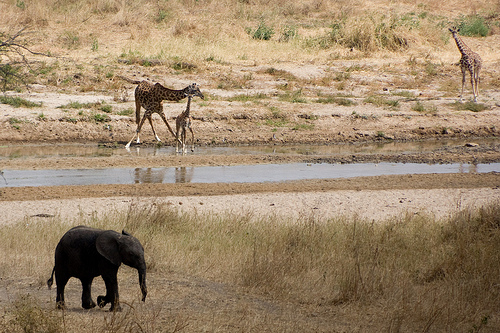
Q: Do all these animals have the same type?
A: No, there are both giraffes and elephants.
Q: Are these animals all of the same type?
A: No, there are both giraffes and elephants.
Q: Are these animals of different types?
A: Yes, they are giraffes and elephants.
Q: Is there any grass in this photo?
A: Yes, there is grass.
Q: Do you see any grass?
A: Yes, there is grass.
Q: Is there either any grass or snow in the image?
A: Yes, there is grass.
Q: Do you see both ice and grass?
A: No, there is grass but no ice.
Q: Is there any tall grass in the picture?
A: Yes, there is tall grass.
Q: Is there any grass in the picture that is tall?
A: Yes, there is grass that is tall.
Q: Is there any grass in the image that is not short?
A: Yes, there is tall grass.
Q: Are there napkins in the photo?
A: No, there are no napkins.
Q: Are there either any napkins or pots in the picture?
A: No, there are no napkins or pots.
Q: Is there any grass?
A: Yes, there is grass.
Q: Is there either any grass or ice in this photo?
A: Yes, there is grass.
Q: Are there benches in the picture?
A: No, there are no benches.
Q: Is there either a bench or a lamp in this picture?
A: No, there are no benches or lamps.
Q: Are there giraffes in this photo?
A: Yes, there is a giraffe.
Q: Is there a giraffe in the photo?
A: Yes, there is a giraffe.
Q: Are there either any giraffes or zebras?
A: Yes, there is a giraffe.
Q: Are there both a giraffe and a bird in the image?
A: No, there is a giraffe but no birds.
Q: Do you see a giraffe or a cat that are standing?
A: Yes, the giraffe is standing.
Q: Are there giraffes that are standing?
A: Yes, there is a giraffe that is standing.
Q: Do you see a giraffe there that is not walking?
A: Yes, there is a giraffe that is standing .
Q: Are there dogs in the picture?
A: No, there are no dogs.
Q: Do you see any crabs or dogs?
A: No, there are no dogs or crabs.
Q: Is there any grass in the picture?
A: Yes, there is grass.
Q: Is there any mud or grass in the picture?
A: Yes, there is grass.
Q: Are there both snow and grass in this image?
A: No, there is grass but no snow.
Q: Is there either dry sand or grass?
A: Yes, there is dry grass.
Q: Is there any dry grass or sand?
A: Yes, there is dry grass.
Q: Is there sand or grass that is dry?
A: Yes, the grass is dry.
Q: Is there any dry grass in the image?
A: Yes, there is dry grass.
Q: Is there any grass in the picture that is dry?
A: Yes, there is grass that is dry.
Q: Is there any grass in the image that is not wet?
A: Yes, there is dry grass.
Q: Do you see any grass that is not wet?
A: Yes, there is dry grass.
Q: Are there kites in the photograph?
A: No, there are no kites.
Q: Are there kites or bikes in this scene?
A: No, there are no kites or bikes.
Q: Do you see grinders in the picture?
A: No, there are no grinders.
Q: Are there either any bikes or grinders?
A: No, there are no grinders or bikes.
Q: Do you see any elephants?
A: Yes, there is an elephant.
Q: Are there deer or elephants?
A: Yes, there is an elephant.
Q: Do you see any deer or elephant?
A: Yes, there is an elephant.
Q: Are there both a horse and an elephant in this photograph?
A: No, there is an elephant but no horses.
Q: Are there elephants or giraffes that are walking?
A: Yes, the elephant is walking.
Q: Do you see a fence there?
A: No, there are no fences.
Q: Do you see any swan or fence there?
A: No, there are no fences or swans.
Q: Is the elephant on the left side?
A: Yes, the elephant is on the left of the image.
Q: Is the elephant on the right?
A: No, the elephant is on the left of the image.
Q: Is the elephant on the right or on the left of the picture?
A: The elephant is on the left of the image.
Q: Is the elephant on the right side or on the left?
A: The elephant is on the left of the image.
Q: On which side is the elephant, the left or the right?
A: The elephant is on the left of the image.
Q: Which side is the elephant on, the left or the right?
A: The elephant is on the left of the image.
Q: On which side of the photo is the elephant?
A: The elephant is on the left of the image.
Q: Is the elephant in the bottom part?
A: Yes, the elephant is in the bottom of the image.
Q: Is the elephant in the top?
A: No, the elephant is in the bottom of the image.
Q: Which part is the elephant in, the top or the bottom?
A: The elephant is in the bottom of the image.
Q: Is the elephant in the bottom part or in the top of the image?
A: The elephant is in the bottom of the image.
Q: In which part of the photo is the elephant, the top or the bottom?
A: The elephant is in the bottom of the image.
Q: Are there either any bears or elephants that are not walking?
A: No, there is an elephant but it is walking.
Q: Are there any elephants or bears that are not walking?
A: No, there is an elephant but it is walking.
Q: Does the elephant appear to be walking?
A: Yes, the elephant is walking.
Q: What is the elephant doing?
A: The elephant is walking.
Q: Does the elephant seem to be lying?
A: No, the elephant is walking.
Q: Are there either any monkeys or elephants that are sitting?
A: No, there is an elephant but it is walking.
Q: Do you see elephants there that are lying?
A: No, there is an elephant but it is walking.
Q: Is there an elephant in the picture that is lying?
A: No, there is an elephant but it is walking.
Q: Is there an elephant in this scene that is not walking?
A: No, there is an elephant but it is walking.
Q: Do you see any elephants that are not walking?
A: No, there is an elephant but it is walking.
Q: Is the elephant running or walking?
A: The elephant is walking.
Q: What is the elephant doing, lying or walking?
A: The elephant is walking.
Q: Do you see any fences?
A: No, there are no fences.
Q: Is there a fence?
A: No, there are no fences.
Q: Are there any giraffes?
A: Yes, there is a giraffe.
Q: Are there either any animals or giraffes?
A: Yes, there is a giraffe.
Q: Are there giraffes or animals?
A: Yes, there is a giraffe.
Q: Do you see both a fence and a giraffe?
A: No, there is a giraffe but no fences.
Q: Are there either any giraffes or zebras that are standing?
A: Yes, the giraffe is standing.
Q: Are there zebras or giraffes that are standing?
A: Yes, the giraffe is standing.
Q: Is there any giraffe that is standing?
A: Yes, there is a giraffe that is standing.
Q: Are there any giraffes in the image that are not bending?
A: Yes, there is a giraffe that is standing.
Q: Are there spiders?
A: No, there are no spiders.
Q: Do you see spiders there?
A: No, there are no spiders.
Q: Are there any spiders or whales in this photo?
A: No, there are no spiders or whales.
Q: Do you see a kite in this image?
A: No, there are no kites.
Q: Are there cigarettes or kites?
A: No, there are no kites or cigarettes.